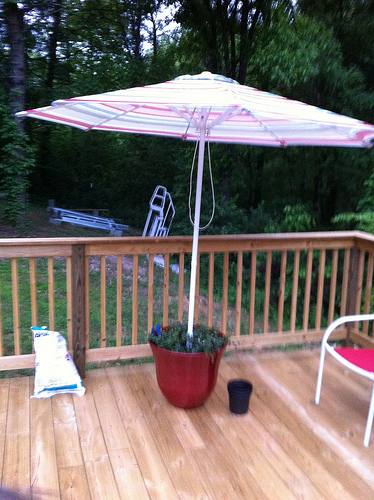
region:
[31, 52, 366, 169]
a striped deck umbrella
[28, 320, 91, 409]
a white bag of plant food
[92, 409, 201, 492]
light brown deck wood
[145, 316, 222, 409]
a red planter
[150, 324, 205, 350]
blue flowers in the pot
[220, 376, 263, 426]
a small black pot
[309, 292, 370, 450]
a red and white deck chair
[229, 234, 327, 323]
wood railing on the deck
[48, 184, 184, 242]
white metal pieces on the ground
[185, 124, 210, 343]
a white metal umbrella pole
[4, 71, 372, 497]
the umbrella on the deck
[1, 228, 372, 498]
the deck is wooden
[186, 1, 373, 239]
the trees with green leaves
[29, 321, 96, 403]
the bag on the deck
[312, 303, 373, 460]
the chair on the deck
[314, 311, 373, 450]
the chair is pink and white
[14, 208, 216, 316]
the ground is sloped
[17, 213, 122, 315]
the grass on the ground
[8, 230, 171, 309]
the grass is green and patchy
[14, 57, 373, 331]
the umbrella is pink and striped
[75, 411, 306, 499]
the ground is wooden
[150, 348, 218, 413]
the vase is red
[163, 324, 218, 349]
the wweds are green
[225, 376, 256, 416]
the vase is black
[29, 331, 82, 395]
the bag is white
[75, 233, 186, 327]
the frame is wooden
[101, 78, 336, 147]
the umbrella is white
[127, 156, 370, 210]
the forest is in the background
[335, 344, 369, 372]
the sofa has a red surface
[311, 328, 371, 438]
the chair is metallic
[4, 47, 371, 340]
The umbrella is open.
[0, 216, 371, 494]
The deck is wooden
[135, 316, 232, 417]
Red flower pot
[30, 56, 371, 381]
The umbrella is in the flower pot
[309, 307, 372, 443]
White chair with a red seat.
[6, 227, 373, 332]
Wooden rail surrounding the deck.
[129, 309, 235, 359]
Flowers growing in the pot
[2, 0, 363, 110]
Photo taken during the day.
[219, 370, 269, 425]
Empty flower pots on the deck.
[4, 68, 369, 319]
Trees surrounding the yard.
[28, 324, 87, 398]
dirt in a bag.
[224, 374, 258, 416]
A planter on the deck.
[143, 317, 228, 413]
A large red planter.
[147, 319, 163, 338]
Small blue flowers.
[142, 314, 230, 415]
FLowers in a pot.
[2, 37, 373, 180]
A large umbrella.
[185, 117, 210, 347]
The post in the dirt.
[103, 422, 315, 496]
A wooden deck.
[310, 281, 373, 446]
A red and white chair.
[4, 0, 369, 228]
Trees in the back yard.